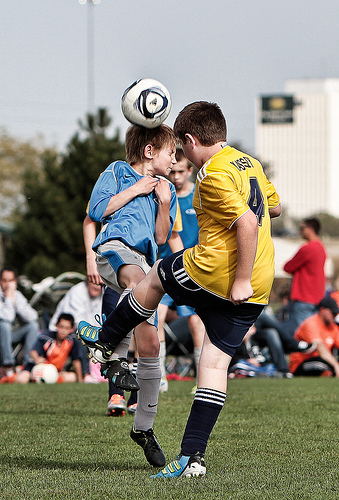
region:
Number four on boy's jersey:
[234, 179, 273, 231]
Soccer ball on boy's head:
[119, 73, 182, 181]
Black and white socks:
[182, 371, 222, 460]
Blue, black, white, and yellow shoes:
[146, 448, 208, 485]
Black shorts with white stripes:
[154, 249, 264, 351]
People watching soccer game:
[0, 237, 336, 379]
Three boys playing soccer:
[77, 79, 284, 479]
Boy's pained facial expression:
[148, 131, 179, 182]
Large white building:
[250, 76, 338, 275]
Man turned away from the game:
[279, 212, 329, 318]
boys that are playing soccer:
[57, 81, 291, 419]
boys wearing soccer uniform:
[65, 71, 291, 418]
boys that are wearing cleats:
[70, 153, 338, 473]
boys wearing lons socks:
[51, 95, 269, 429]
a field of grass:
[20, 364, 205, 496]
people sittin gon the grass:
[51, 294, 329, 419]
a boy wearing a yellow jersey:
[162, 100, 334, 334]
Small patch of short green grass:
[5, 466, 40, 499]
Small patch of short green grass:
[39, 456, 60, 495]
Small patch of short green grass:
[59, 455, 88, 497]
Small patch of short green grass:
[76, 452, 119, 494]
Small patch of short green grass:
[217, 453, 237, 475]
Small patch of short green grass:
[296, 439, 331, 491]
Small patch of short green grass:
[244, 398, 278, 438]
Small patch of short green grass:
[56, 382, 81, 411]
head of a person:
[166, 89, 238, 172]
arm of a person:
[206, 184, 274, 262]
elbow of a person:
[231, 212, 267, 235]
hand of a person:
[220, 276, 263, 317]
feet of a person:
[143, 445, 204, 495]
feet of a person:
[116, 421, 174, 470]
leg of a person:
[115, 306, 181, 417]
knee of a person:
[142, 333, 179, 359]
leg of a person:
[101, 268, 180, 346]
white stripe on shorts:
[176, 272, 190, 283]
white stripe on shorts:
[173, 270, 184, 275]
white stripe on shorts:
[172, 265, 180, 272]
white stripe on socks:
[191, 385, 222, 395]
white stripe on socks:
[189, 394, 217, 401]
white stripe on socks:
[127, 288, 152, 309]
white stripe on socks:
[124, 293, 147, 315]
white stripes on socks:
[128, 290, 154, 318]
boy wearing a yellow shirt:
[180, 104, 281, 351]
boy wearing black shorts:
[177, 98, 289, 328]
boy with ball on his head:
[109, 68, 177, 228]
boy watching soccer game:
[39, 302, 68, 379]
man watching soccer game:
[1, 261, 30, 373]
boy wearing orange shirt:
[40, 298, 72, 373]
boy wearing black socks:
[172, 97, 284, 454]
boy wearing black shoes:
[57, 105, 167, 461]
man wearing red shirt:
[284, 206, 329, 310]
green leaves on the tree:
[49, 240, 70, 266]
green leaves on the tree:
[25, 228, 46, 254]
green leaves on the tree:
[44, 227, 84, 252]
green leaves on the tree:
[102, 122, 124, 150]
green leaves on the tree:
[82, 119, 108, 150]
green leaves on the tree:
[73, 149, 91, 165]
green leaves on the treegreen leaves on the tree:
[22, 148, 42, 166]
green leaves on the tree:
[64, 163, 80, 195]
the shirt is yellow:
[171, 133, 290, 308]